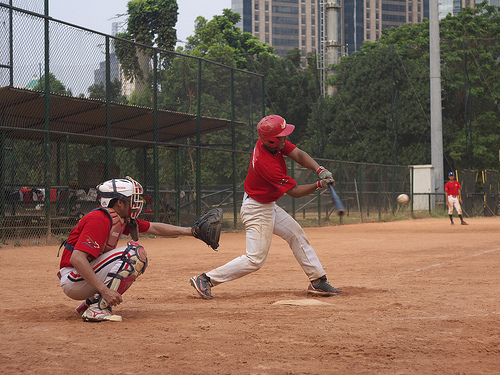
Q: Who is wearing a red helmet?
A: The batter.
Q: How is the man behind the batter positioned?
A: Crouching.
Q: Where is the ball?
A: In mid air.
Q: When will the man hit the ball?
A: When it comes close enough.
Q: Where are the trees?
A: Behind the fence.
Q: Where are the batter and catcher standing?
A: First base.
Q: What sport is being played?
A: Baseball.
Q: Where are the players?
A: On a baseball field.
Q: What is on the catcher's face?
A: A mask.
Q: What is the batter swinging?
A: A bat.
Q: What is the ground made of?
A: Dirt.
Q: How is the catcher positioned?
A: Squatting.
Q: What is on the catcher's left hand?
A: A catcher's mitt.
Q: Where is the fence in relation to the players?
A: Behind them.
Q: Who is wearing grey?
A: The man is.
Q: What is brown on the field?
A: The dirt is brown.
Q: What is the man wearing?
A: A red shirt.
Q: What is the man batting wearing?
A: A red shirt.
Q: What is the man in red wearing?
A: A shirt.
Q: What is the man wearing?
A: A shirt and helmet.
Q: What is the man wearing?
A: A red shirt and pants.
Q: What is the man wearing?
A: A red shirt.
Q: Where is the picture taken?
A: Baseball game.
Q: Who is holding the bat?
A: The batter.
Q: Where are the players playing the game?
A: Baseball field.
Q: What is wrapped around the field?
A: Fence.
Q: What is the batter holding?
A: A bat.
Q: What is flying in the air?
A: A ball.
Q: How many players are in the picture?
A: Three.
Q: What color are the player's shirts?
A: Red.